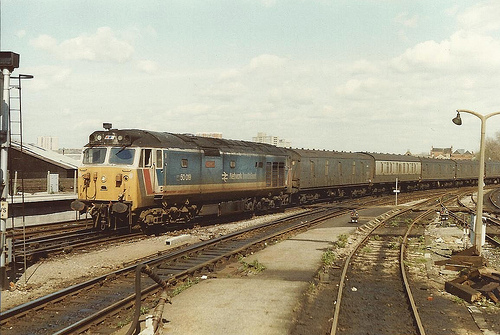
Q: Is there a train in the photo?
A: Yes, there is a train.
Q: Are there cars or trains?
A: Yes, there is a train.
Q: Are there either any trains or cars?
A: Yes, there is a train.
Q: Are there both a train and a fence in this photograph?
A: Yes, there are both a train and a fence.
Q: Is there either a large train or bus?
A: Yes, there is a large train.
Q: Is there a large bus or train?
A: Yes, there is a large train.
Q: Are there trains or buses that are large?
A: Yes, the train is large.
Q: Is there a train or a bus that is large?
A: Yes, the train is large.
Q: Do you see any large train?
A: Yes, there is a large train.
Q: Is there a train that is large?
A: Yes, there is a train that is large.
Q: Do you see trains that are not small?
A: Yes, there is a large train.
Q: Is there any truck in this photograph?
A: No, there are no trucks.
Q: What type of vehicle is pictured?
A: The vehicle is a train.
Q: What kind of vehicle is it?
A: The vehicle is a train.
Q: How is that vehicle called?
A: This is a train.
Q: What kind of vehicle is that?
A: This is a train.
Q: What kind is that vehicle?
A: This is a train.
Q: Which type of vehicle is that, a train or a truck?
A: This is a train.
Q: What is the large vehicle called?
A: The vehicle is a train.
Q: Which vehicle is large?
A: The vehicle is a train.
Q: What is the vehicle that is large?
A: The vehicle is a train.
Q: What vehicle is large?
A: The vehicle is a train.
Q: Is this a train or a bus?
A: This is a train.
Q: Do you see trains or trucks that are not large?
A: No, there is a train but it is large.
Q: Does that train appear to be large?
A: Yes, the train is large.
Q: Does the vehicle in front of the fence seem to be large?
A: Yes, the train is large.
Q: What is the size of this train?
A: The train is large.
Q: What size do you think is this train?
A: The train is large.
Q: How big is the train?
A: The train is large.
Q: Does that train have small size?
A: No, the train is large.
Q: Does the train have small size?
A: No, the train is large.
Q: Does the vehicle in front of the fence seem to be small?
A: No, the train is large.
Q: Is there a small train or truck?
A: No, there is a train but it is large.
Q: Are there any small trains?
A: No, there is a train but it is large.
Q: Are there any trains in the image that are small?
A: No, there is a train but it is large.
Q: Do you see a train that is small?
A: No, there is a train but it is large.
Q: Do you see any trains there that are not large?
A: No, there is a train but it is large.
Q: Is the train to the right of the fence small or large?
A: The train is large.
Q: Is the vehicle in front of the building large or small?
A: The train is large.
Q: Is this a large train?
A: Yes, this is a large train.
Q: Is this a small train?
A: No, this is a large train.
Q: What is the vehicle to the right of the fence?
A: The vehicle is a train.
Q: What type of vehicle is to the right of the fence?
A: The vehicle is a train.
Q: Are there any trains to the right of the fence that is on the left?
A: Yes, there is a train to the right of the fence.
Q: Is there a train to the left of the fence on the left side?
A: No, the train is to the right of the fence.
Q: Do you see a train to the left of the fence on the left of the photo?
A: No, the train is to the right of the fence.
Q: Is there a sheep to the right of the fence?
A: No, there is a train to the right of the fence.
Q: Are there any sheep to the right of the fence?
A: No, there is a train to the right of the fence.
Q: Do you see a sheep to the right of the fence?
A: No, there is a train to the right of the fence.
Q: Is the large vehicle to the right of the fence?
A: Yes, the train is to the right of the fence.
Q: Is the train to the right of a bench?
A: No, the train is to the right of the fence.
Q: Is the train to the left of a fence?
A: No, the train is to the right of a fence.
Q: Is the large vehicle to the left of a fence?
A: No, the train is to the right of a fence.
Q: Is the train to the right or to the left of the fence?
A: The train is to the right of the fence.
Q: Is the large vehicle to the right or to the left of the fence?
A: The train is to the right of the fence.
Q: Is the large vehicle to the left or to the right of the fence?
A: The train is to the right of the fence.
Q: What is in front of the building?
A: The train is in front of the building.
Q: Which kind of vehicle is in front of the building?
A: The vehicle is a train.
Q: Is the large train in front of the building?
A: Yes, the train is in front of the building.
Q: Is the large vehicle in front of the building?
A: Yes, the train is in front of the building.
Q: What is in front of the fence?
A: The train is in front of the fence.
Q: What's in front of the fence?
A: The train is in front of the fence.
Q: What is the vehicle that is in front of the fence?
A: The vehicle is a train.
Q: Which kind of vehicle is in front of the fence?
A: The vehicle is a train.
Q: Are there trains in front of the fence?
A: Yes, there is a train in front of the fence.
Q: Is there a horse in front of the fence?
A: No, there is a train in front of the fence.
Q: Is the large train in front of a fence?
A: Yes, the train is in front of a fence.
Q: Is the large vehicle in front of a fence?
A: Yes, the train is in front of a fence.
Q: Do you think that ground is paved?
A: Yes, the ground is paved.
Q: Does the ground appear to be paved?
A: Yes, the ground is paved.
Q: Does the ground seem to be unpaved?
A: No, the ground is paved.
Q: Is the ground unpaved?
A: No, the ground is paved.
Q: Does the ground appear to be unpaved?
A: No, the ground is paved.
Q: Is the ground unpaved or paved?
A: The ground is paved.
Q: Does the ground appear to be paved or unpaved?
A: The ground is paved.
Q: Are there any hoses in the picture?
A: No, there are no hoses.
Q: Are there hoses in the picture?
A: No, there are no hoses.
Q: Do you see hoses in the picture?
A: No, there are no hoses.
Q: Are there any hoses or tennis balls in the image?
A: No, there are no hoses or tennis balls.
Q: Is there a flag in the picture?
A: No, there are no flags.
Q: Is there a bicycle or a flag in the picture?
A: No, there are no flags or bicycles.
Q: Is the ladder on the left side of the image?
A: Yes, the ladder is on the left of the image.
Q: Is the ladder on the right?
A: No, the ladder is on the left of the image.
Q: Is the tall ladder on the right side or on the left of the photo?
A: The ladder is on the left of the image.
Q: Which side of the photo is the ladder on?
A: The ladder is on the left of the image.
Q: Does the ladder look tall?
A: Yes, the ladder is tall.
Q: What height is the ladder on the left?
A: The ladder is tall.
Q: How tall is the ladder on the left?
A: The ladder is tall.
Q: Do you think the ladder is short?
A: No, the ladder is tall.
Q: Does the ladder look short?
A: No, the ladder is tall.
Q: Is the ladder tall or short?
A: The ladder is tall.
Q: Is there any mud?
A: Yes, there is mud.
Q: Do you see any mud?
A: Yes, there is mud.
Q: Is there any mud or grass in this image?
A: Yes, there is mud.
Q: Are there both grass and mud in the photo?
A: Yes, there are both mud and grass.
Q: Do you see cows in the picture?
A: No, there are no cows.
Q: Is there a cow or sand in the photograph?
A: No, there are no cows or sand.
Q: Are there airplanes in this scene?
A: No, there are no airplanes.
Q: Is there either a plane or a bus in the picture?
A: No, there are no airplanes or buses.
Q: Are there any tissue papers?
A: No, there are no tissue papers.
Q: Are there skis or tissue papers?
A: No, there are no tissue papers or skis.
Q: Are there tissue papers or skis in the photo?
A: No, there are no tissue papers or skis.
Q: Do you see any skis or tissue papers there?
A: No, there are no tissue papers or skis.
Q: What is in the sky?
A: The clouds are in the sky.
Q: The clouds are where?
A: The clouds are in the sky.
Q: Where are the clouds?
A: The clouds are in the sky.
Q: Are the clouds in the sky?
A: Yes, the clouds are in the sky.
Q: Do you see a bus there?
A: No, there are no buses.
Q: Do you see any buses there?
A: No, there are no buses.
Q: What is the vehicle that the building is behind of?
A: The vehicle is a train.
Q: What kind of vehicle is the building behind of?
A: The building is behind the train.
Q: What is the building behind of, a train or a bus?
A: The building is behind a train.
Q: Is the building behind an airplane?
A: No, the building is behind a train.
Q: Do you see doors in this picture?
A: Yes, there is a door.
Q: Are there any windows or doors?
A: Yes, there is a door.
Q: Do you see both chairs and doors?
A: No, there is a door but no chairs.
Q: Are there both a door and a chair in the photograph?
A: No, there is a door but no chairs.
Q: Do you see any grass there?
A: Yes, there is grass.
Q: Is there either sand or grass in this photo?
A: Yes, there is grass.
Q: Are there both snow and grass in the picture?
A: No, there is grass but no snow.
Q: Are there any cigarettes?
A: No, there are no cigarettes.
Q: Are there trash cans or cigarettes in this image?
A: No, there are no cigarettes or trash cans.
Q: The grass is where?
A: The grass is on the ground.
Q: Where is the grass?
A: The grass is on the ground.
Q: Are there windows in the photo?
A: Yes, there is a window.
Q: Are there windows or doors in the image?
A: Yes, there is a window.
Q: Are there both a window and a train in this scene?
A: Yes, there are both a window and a train.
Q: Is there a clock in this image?
A: No, there are no clocks.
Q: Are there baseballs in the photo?
A: No, there are no baseballs.